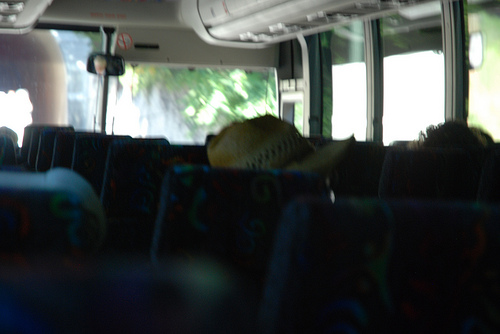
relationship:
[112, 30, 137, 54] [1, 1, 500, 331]
sticker on bus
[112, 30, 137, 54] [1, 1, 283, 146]
sticker at front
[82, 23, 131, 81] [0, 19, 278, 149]
mirror in window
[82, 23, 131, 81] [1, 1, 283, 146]
mirror in front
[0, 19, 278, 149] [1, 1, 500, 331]
window on bus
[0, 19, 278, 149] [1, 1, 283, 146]
window in front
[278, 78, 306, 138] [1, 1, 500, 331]
door on bus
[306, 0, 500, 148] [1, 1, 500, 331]
windows on bus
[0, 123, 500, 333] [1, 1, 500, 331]
seats in rows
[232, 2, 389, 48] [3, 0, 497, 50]
lights on ceiling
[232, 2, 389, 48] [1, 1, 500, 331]
lights in bus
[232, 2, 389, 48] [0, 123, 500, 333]
lights above seats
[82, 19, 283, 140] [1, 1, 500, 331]
leaves outside bus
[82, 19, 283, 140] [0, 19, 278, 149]
leaves on tree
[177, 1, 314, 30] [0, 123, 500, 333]
storage above seats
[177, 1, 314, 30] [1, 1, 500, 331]
storage in bus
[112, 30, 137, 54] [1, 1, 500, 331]
sign in bus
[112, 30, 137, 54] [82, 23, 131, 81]
sign above mirror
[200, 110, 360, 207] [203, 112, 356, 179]
person wearing hat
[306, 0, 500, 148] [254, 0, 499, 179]
windows on side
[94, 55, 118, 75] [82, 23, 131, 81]
reflection in mirror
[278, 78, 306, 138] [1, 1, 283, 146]
door in front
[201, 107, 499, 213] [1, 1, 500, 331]
people on bus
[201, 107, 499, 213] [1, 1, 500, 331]
people in bus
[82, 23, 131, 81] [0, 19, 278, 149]
mirror on window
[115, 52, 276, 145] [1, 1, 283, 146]
tree in front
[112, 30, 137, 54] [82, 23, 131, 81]
sign near mirror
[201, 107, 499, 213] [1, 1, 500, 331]
passengers on bus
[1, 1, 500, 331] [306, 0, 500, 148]
bus has windows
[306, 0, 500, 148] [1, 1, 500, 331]
windows all bus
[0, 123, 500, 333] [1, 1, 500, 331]
seats on bus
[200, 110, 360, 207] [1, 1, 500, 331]
person on bus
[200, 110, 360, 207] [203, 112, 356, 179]
person has hat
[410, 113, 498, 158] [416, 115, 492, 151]
passenger has hair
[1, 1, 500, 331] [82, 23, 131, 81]
bus has mirror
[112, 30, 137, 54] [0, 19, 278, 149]
sign near window